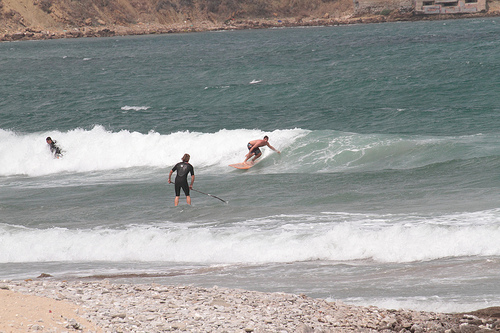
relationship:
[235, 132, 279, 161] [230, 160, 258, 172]
man on board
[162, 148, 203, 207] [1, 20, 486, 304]
woman in water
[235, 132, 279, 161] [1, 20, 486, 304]
man in water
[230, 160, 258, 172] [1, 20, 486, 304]
board in water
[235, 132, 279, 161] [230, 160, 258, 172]
man above board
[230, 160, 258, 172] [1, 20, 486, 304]
board above water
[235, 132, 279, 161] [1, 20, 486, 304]
man above water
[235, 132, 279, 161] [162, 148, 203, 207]
man near woman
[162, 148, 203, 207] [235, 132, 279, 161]
woman near man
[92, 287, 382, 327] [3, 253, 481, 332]
rock on beach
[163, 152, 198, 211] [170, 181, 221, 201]
man holding paddle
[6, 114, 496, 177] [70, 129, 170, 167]
waves have tops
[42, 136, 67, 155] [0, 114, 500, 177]
person engulfed in waves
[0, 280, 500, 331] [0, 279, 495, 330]
rock on shore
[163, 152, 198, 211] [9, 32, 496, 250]
man in water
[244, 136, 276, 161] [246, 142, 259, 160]
man wearing shorts